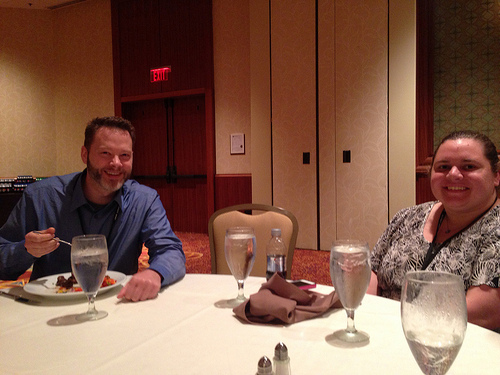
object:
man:
[1, 114, 190, 305]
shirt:
[1, 175, 187, 290]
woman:
[363, 130, 500, 331]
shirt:
[362, 200, 499, 306]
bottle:
[267, 229, 285, 280]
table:
[0, 270, 499, 375]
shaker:
[253, 355, 276, 374]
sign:
[150, 65, 171, 83]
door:
[110, 0, 217, 231]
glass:
[70, 233, 110, 321]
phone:
[289, 278, 315, 290]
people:
[2, 116, 186, 304]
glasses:
[396, 267, 468, 375]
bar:
[127, 172, 205, 184]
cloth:
[232, 272, 343, 326]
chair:
[209, 203, 299, 279]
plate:
[20, 269, 129, 301]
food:
[54, 270, 116, 294]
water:
[71, 254, 107, 295]